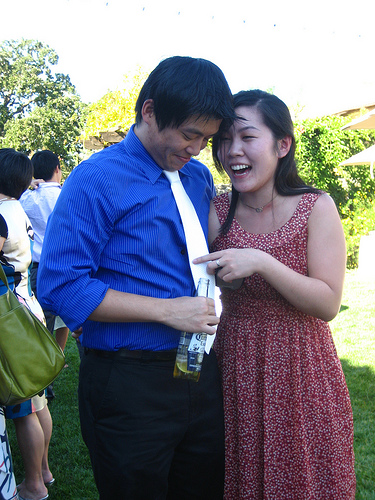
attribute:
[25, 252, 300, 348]
people — standing, together, asian, having fun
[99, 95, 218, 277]
man — laughing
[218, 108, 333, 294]
woman — laughing, standing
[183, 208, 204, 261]
tie — gray, white, dress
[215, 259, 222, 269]
ring — silver, worn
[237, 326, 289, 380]
dress — pink, red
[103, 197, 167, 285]
shirt — blue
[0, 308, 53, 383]
purse — green, big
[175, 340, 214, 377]
beer — empty, held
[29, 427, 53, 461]
calf — bare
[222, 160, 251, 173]
teeth — white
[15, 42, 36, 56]
leaves — green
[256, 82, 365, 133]
roof — part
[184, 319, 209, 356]
bottle — clear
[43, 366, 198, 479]
pants — black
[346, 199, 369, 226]
bushes — green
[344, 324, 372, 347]
grass — green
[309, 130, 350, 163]
tree — background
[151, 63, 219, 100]
hair — black